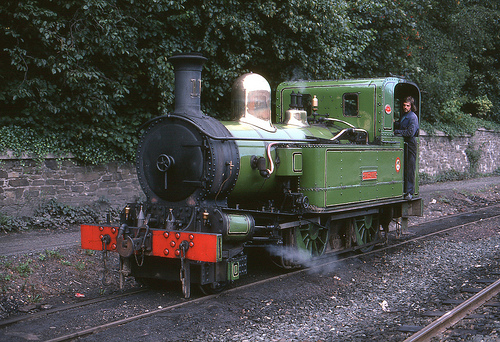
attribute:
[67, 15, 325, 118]
trees — green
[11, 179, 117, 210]
stone — brown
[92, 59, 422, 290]
train — small, green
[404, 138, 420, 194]
pants — black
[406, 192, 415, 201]
shoes — black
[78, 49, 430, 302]
train — green, shiny, black, red, little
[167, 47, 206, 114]
stack — smoke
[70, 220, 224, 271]
bumper — red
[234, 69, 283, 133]
part — gold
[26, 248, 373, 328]
tracks — train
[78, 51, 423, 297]
engine — train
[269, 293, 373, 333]
ballast — grey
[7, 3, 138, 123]
tree — green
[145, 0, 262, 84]
tree — green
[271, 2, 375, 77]
tree — green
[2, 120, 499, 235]
wall — grey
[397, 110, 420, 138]
shirt — blue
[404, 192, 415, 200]
shoes — black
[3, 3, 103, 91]
trees — thick, green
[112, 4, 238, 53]
trees — thick, green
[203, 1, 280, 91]
trees — thick, green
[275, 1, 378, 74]
trees — thick, green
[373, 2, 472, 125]
trees — thick, green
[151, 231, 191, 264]
sticker — round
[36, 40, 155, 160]
tree — green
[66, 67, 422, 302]
train — green, red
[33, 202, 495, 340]
train tracks — rusty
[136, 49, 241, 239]
front — black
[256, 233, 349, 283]
smoke — white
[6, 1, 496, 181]
bushes — dark green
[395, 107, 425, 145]
t-shirt — blue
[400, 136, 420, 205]
jeans — dark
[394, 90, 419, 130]
man's hair — dark, large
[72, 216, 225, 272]
bumper — red